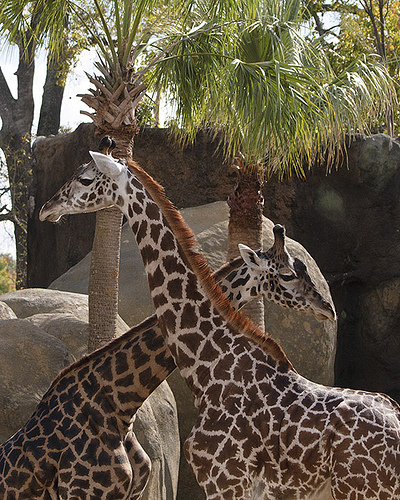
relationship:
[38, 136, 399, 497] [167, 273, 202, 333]
giraffe has spots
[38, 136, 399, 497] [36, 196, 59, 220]
giraffe has nose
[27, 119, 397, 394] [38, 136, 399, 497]
boulders are behind giraffe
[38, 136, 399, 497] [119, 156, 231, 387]
giraffe has long neck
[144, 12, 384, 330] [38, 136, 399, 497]
tree behind giraffe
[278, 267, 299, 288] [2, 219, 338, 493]
right eye of giraffe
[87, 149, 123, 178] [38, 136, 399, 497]
left ear of giraffe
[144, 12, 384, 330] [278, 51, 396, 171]
tree has leaves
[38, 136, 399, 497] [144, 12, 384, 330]
giraffe by tree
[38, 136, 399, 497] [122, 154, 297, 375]
giraffe has mane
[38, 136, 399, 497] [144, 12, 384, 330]
giraffe under tree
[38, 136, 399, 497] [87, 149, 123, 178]
giraffe has left ear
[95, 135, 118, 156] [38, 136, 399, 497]
black knobs are on top of giraffe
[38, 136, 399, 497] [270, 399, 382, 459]
giraffe has white lines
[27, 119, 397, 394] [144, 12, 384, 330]
boulders are behind tree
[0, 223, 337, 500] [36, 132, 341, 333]
giraffe face opposite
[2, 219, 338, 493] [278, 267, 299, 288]
giraffe has right eye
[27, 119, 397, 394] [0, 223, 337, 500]
boulders are behind giraffe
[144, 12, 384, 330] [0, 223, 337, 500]
tree behind giraffe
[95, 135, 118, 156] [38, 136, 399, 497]
black knobs are on giraffe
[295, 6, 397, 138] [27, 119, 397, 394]
trees are behind boulders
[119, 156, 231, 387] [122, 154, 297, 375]
long neck has mane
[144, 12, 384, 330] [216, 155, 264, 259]
tree has bark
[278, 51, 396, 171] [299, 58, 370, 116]
leaves have stems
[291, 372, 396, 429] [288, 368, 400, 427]
back has reflection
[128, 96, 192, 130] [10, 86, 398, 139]
treetops are on horizon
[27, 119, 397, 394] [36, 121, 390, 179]
boulders have shadows